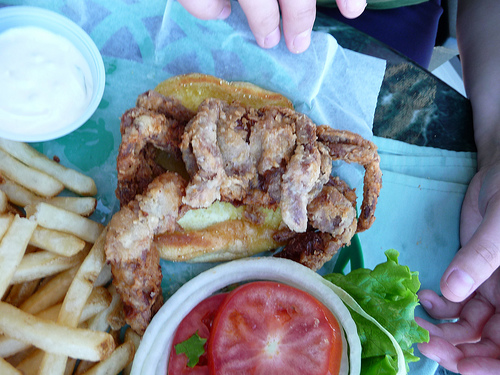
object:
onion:
[125, 253, 369, 375]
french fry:
[59, 249, 102, 324]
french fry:
[36, 202, 94, 242]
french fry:
[28, 229, 84, 261]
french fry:
[5, 162, 65, 198]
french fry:
[5, 304, 116, 366]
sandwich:
[110, 70, 377, 267]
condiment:
[0, 26, 85, 133]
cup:
[0, 4, 107, 149]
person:
[172, 0, 498, 373]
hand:
[173, 0, 371, 56]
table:
[0, 3, 487, 374]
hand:
[410, 170, 498, 374]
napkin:
[308, 133, 480, 375]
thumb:
[434, 193, 499, 304]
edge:
[288, 71, 328, 120]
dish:
[0, 15, 379, 323]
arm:
[450, 1, 498, 162]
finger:
[413, 289, 446, 320]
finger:
[404, 312, 480, 339]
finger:
[419, 337, 452, 367]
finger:
[451, 355, 498, 373]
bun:
[124, 69, 308, 263]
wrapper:
[3, 1, 378, 287]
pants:
[359, 3, 441, 67]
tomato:
[209, 281, 339, 373]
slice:
[210, 283, 343, 375]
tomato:
[176, 304, 214, 373]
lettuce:
[333, 251, 427, 375]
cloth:
[249, 44, 370, 92]